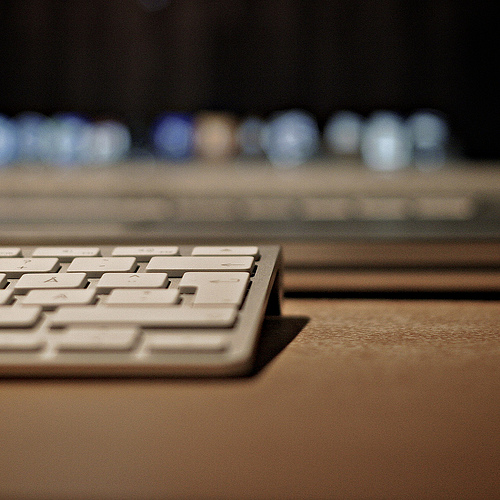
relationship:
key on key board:
[184, 267, 248, 309] [0, 241, 288, 379]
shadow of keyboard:
[244, 311, 314, 378] [62, 214, 349, 368]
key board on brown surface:
[5, 236, 322, 408] [108, 285, 455, 485]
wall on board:
[389, 155, 428, 197] [38, 230, 324, 386]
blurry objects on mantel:
[248, 99, 465, 197] [131, 146, 499, 250]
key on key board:
[142, 253, 255, 271] [0, 241, 288, 379]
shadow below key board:
[244, 311, 314, 378] [0, 241, 288, 379]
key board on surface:
[0, 241, 288, 379] [300, 284, 470, 430]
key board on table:
[0, 241, 288, 379] [0, 243, 497, 495]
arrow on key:
[191, 248, 259, 281] [142, 253, 255, 271]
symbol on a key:
[126, 272, 142, 280] [5, 256, 60, 270]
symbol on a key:
[15, 262, 29, 270] [71, 255, 136, 271]